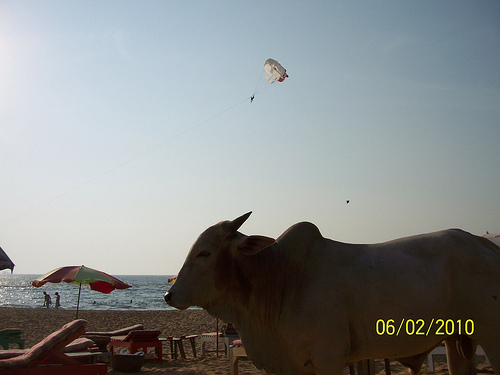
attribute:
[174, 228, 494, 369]
bull — tan, brown, looking, white, standing, animal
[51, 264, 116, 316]
umbrella — big, colored, multicolored, opened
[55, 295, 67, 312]
people — walking, standing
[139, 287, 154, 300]
water — blue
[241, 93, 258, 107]
person — parasailing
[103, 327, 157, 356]
chairs — long, outdoors, empty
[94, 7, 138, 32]
sky — bright, blue, clear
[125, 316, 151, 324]
sand — brown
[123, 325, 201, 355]
furniture — outdoors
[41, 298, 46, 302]
hand — reaching